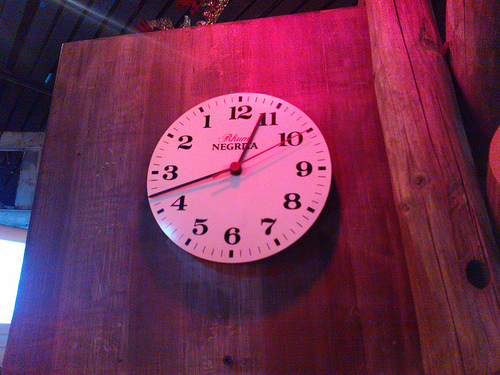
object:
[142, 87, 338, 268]
clock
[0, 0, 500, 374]
wall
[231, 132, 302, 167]
hand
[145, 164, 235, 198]
hand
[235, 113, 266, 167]
hand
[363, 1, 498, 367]
post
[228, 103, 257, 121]
12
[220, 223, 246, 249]
6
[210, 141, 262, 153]
words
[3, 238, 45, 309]
area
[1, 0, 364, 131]
ceiling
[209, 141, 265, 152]
writing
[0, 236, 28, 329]
light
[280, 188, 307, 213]
8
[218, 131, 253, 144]
lettering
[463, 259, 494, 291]
hole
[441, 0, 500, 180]
pole